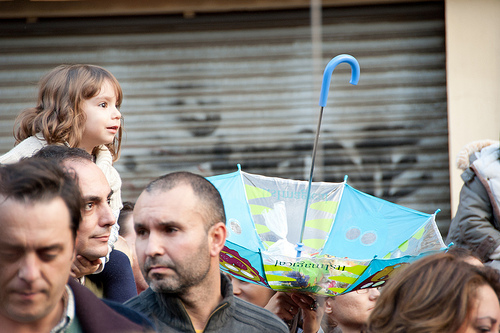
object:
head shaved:
[132, 170, 224, 222]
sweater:
[121, 271, 288, 332]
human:
[121, 171, 290, 332]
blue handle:
[319, 54, 360, 108]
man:
[30, 144, 117, 300]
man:
[0, 155, 150, 333]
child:
[0, 63, 124, 279]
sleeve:
[457, 168, 499, 261]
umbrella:
[185, 55, 454, 299]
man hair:
[132, 170, 228, 294]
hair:
[0, 157, 86, 255]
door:
[0, 0, 448, 238]